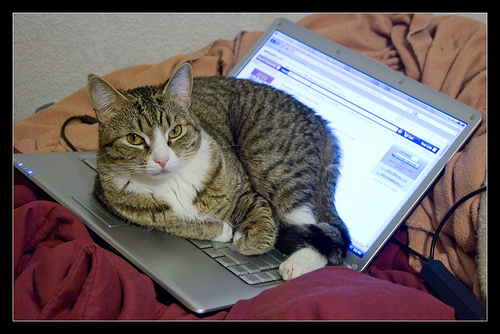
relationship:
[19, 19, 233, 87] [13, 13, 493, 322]
carpet in house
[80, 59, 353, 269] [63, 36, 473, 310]
cat on laptop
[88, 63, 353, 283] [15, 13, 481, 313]
cat on laptop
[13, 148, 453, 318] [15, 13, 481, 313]
comforter under laptop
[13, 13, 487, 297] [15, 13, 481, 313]
blanket under laptop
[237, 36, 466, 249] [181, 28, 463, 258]
image on screen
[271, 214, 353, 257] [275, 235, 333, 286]
tail wrapped around foot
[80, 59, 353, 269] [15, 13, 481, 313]
cat on laptop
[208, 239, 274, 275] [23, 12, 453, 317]
buttons on keyboard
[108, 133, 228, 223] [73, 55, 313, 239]
chest on cat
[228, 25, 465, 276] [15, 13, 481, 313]
screen on laptop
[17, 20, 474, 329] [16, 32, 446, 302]
blanket under computer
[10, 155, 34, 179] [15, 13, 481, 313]
lights on front of laptop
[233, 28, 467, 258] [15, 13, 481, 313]
screen on laptop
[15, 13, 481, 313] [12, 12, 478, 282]
laptop on blanket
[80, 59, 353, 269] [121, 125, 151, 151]
cat has eye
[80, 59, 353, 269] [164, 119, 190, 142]
cat has eye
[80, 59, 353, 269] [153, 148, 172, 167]
cat has nose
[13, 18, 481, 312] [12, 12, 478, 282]
laptop on blanket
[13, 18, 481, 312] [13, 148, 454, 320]
laptop on comforter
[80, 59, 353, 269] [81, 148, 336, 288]
cat on top of keyboard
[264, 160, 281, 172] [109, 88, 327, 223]
stripes are on fur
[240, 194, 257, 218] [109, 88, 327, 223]
stripes are on fur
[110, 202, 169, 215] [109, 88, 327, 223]
stripes are on fur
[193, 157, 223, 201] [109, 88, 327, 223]
stripes are on fur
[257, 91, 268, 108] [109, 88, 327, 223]
stripes are on fur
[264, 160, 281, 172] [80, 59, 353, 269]
stripes are on cat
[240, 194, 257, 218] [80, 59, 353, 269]
stripes are on cat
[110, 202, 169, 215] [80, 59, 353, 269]
stripes are on cat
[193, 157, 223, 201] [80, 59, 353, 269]
stripes are on cat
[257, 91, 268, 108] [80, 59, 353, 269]
stripes are on cat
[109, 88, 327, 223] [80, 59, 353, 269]
fur are on cat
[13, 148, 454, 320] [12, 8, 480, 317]
comforter on bed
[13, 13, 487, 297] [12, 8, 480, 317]
blanket are on bed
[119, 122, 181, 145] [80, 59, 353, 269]
eyes are on cat